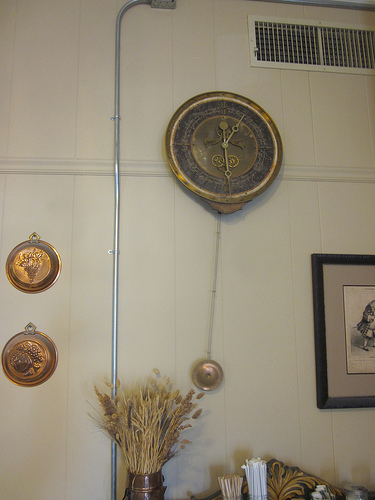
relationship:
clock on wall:
[166, 88, 283, 218] [3, 2, 370, 499]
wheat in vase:
[92, 376, 204, 476] [121, 464, 168, 500]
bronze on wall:
[5, 322, 59, 387] [3, 2, 370, 499]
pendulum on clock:
[189, 208, 228, 391] [166, 88, 283, 218]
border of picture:
[311, 252, 373, 412] [324, 265, 370, 402]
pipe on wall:
[109, 0, 152, 500] [122, 175, 207, 371]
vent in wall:
[246, 13, 372, 70] [274, 85, 373, 164]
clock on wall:
[166, 88, 283, 218] [271, 86, 373, 148]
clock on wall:
[164, 88, 284, 216] [289, 71, 374, 161]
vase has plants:
[122, 464, 167, 498] [92, 369, 203, 467]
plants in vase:
[92, 369, 203, 467] [126, 470, 166, 498]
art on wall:
[310, 250, 375, 410] [291, 188, 374, 247]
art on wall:
[310, 250, 375, 410] [281, 182, 374, 248]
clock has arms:
[164, 88, 284, 216] [217, 111, 247, 185]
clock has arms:
[164, 88, 284, 216] [218, 111, 243, 180]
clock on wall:
[166, 88, 283, 218] [273, 87, 358, 168]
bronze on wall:
[0, 322, 59, 388] [4, 177, 111, 245]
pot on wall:
[4, 231, 67, 296] [4, 177, 111, 245]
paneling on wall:
[118, 172, 185, 381] [126, 207, 216, 323]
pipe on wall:
[109, 0, 152, 500] [121, 176, 204, 356]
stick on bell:
[207, 211, 219, 360] [194, 360, 223, 391]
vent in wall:
[246, 13, 375, 76] [65, 25, 253, 88]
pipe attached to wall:
[109, 207, 121, 372] [140, 213, 298, 344]